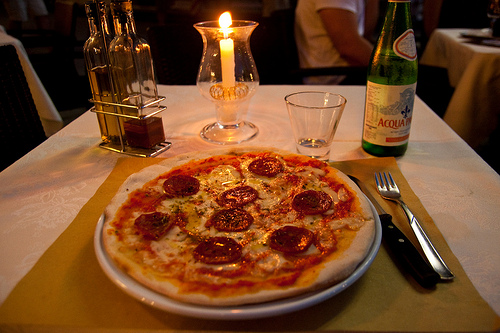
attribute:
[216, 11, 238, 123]
candle — bright, white, lit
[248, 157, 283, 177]
pepperoni — red, baked, crispy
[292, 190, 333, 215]
pepperoni — red, baked, crispy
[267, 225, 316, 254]
pepperoni — red, baked, crispy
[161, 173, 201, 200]
pepperoni — red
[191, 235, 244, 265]
pepperoni — red, baked, crispy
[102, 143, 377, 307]
pizza — small, medium, cooked, round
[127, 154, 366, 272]
cheese — melted, mozzerella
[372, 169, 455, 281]
fork — silver, stainless steel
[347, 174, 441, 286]
knife — silver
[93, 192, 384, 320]
plate — round, white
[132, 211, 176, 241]
pepperoni — baked, crispy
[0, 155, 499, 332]
mat — gold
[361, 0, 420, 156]
bottle — green, glass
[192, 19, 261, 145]
container — glass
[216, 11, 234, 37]
flame — bright, burning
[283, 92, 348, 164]
glass — clear, empty, small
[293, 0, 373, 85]
person — sitting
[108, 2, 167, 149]
container — glass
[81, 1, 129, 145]
container — glass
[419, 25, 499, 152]
table — another, nearby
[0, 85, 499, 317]
tablecloth — white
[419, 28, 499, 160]
tablecloth — white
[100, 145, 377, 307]
crust — white